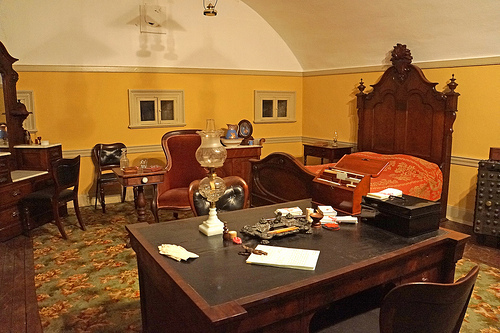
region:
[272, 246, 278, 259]
edge of a table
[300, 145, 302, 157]
part of a house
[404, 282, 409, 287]
part of a chair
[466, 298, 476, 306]
part of a floor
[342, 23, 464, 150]
A very ornate wood headboard.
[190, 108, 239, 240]
An oil lamp on the desk.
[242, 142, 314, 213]
A very ornate foot board.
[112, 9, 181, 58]
Shadow on the wall caused by the lamp.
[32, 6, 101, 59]
White wall in the bedroom.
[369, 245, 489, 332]
Chair behind the desk.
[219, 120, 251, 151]
Wash bowl on the stand.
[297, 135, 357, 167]
Table beside the bed.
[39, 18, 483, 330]
a very elegant room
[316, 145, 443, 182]
the bedspread is orange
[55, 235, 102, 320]
the area rug is flowered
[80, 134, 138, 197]
the chair appears to be wood &leather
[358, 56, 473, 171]
a huge headboard on the bed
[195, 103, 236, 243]
the kerosene lantern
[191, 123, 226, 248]
the base appears to be marble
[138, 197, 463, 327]
the desk has an inlaid desk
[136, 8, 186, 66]
a shadow of the ceiling lantern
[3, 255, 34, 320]
the floor is wooden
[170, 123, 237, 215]
clear lamp on table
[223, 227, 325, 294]
white papers on table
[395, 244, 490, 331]
brown chair at table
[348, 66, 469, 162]
large brown headboard of bed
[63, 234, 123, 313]
gold and green carpet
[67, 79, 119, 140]
wall is dark yellow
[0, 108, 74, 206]
brown chair in corner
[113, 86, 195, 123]
white frames around windows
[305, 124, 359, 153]
small table near bed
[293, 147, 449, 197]
red blanket on bed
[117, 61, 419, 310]
the view is in a bbedroom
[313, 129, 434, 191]
the bed is covered in red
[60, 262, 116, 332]
the floor is covered with a carpet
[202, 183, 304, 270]
papers are left on he table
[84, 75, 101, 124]
the wall is yellow in color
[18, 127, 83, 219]
the furnitus are made of wood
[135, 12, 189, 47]
shadow of the lights on the wall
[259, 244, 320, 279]
the papr is white in color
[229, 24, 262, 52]
wall is white in color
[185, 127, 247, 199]
the glassis colorles